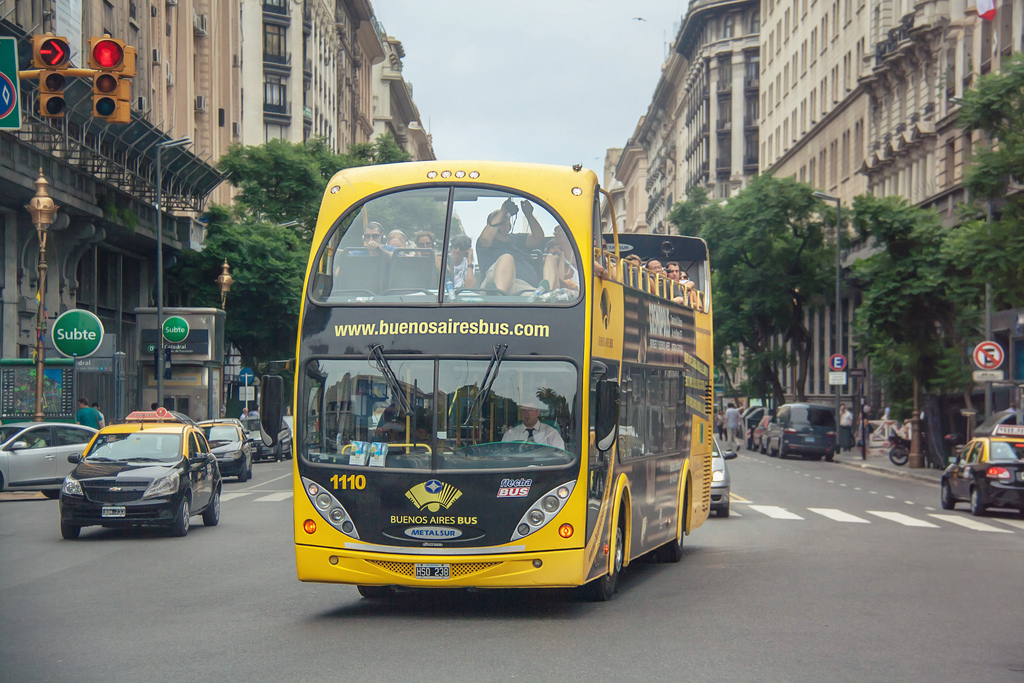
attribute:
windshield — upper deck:
[305, 172, 590, 306]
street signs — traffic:
[972, 334, 1008, 398]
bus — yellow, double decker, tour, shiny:
[274, 145, 723, 621]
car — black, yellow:
[47, 413, 235, 547]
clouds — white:
[406, 24, 710, 181]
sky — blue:
[406, 24, 710, 181]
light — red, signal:
[78, 33, 192, 138]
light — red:
[31, 27, 112, 155]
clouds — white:
[455, 39, 703, 188]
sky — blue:
[455, 39, 703, 188]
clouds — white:
[458, 21, 645, 167]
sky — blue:
[458, 21, 645, 167]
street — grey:
[748, 486, 824, 632]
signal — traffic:
[55, 39, 195, 141]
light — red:
[96, 27, 233, 149]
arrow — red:
[8, 45, 119, 129]